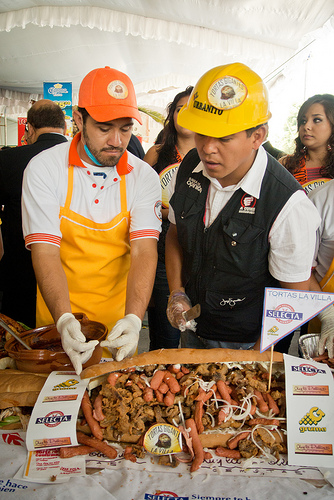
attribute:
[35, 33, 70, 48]
roof — white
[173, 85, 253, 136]
hat — yellow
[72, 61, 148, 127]
hat — orange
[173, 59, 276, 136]
hat — yellow, hard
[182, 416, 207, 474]
hot dog — pink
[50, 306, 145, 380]
gloves — white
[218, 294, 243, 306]
signature — white, cursive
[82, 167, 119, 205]
button — orange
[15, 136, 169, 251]
shirt — white, orange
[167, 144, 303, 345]
vest — black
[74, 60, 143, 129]
cap — orange